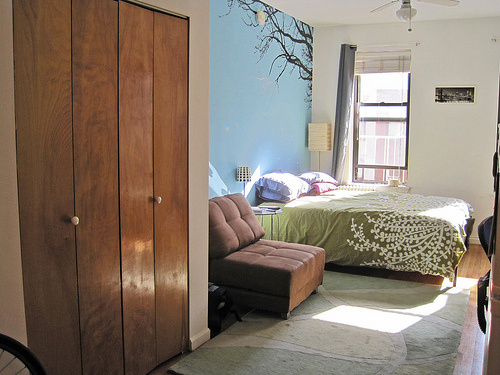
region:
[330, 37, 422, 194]
a window with a gray curtain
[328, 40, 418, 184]
a window slightly open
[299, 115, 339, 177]
a lamp with a square shade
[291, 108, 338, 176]
a lamp in the corner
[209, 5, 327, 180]
a blue wall with a tree decoration on it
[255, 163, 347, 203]
two stacks of pillows on the bed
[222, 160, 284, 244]
a circular side table with a lamp on it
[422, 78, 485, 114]
black and white picture hanging on the wall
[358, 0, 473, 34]
a ceiling fan with a lamp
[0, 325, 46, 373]
wheel of a bicycle in the corner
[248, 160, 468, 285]
Bed in the background.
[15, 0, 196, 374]
Brown closet doors.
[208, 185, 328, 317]
Brown chair by the bed.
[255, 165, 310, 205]
Pillows on the bed.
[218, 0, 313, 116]
Tree branches painted on the wall.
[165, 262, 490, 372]
Rug on the floor.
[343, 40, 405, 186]
Window on the wall.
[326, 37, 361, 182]
Gray drapes on the wall.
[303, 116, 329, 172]
Lamp on the corner.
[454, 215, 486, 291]
Hardwood floor on the ground.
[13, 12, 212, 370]
four door wooden closet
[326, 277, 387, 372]
gray and white colored rug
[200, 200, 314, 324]
brown colored love seat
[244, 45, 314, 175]
light blue colored wall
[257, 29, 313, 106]
tree decal on wall corner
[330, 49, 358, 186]
gray colored curtains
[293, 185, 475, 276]
green and white floral designed cover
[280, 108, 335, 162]
cream colored lamp shade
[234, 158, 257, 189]
polka dot designed lamp shade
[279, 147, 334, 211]
purple and pink pillows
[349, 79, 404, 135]
this is a window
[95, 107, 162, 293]
this is a dresser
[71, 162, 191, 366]
this is a closet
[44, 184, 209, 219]
these are two brown knobs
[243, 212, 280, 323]
this is a sofa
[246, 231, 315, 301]
this is brown sofa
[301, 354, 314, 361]
this is a rug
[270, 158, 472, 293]
this is a bed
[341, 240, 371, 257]
the bed is green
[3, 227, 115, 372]
this is a wheel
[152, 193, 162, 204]
Small knob on closet door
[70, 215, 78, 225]
Small knob on closet door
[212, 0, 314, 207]
Wall behind bed is blue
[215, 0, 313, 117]
Black tree decal on blue wall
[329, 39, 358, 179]
Gray curtain on window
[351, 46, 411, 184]
Window next to bed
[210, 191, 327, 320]
Brown chair next to bed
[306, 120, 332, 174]
Lamp next to gray curtain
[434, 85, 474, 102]
Poster next to window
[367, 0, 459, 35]
Ceiling fan above bed